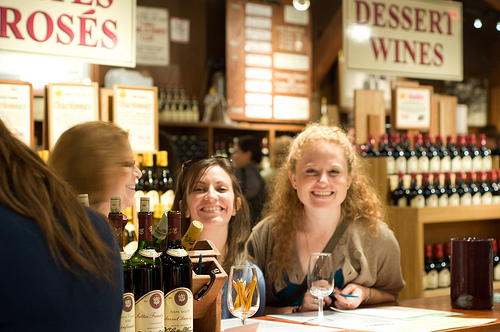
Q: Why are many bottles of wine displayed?
A: To be sold.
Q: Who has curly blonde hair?
A: Woman on right.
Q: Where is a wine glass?
A: On countertop.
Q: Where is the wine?
A: In bottles.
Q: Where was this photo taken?
A: In a winery.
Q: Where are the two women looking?
A: At the camera.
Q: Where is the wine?
A: On the shelves.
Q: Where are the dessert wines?
A: In the back on the right.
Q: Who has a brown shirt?
A: The woman at the bar.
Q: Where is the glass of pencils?
A: On the bar.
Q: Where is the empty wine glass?
A: In front of the woman.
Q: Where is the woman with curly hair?
A: At the bar.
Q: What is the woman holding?
A: A blue pen.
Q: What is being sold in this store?
A: Wine.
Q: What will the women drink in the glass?
A: Wine.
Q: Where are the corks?
A: Wine bottles.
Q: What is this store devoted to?
A: Wine.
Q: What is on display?
A: Wine.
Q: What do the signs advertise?
A: Types of wine.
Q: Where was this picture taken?
A: A wine shop.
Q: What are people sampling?
A: Wine.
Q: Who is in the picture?
A: Women.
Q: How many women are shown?
A: Three.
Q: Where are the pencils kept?
A: A wine glass.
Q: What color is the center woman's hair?
A: Brown.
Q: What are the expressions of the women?
A: Smiling.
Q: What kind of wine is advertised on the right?
A: Dessert.